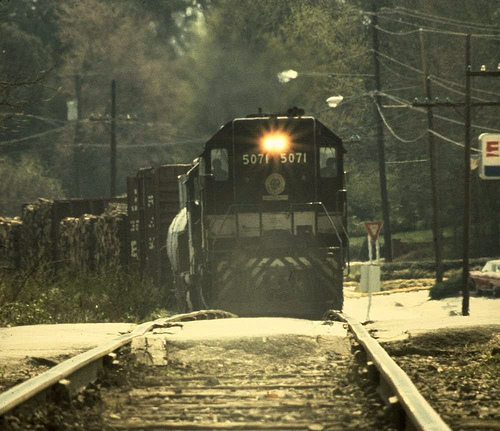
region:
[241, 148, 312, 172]
The numbers on the front of the train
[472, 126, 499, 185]
The large sign by the telephone wires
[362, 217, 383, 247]
The red and white yield sign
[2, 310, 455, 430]
The tracks the train is on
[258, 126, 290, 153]
The light on the front of the train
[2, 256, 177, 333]
The tall grass next to the train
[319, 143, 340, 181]
The window on the right side of the train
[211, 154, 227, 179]
The person shown in the left window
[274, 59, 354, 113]
The street lights seen above the train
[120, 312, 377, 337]
Where road crosses the train tracks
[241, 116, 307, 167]
The train's headlight.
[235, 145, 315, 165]
The train's number.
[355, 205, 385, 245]
A triangular street sign.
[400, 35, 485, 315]
A slender utility pole.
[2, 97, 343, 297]
The train is hauling cargo.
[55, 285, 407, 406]
Train tracks.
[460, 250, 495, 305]
A parked car.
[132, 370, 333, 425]
Wooden planks in gravel.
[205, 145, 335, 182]
The train's conductors can be seen in the windows.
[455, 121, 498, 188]
A large business sign.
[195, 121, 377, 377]
train coming down tracks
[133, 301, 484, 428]
train track crossing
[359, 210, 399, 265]
red and white yield sign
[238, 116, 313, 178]
light on front of train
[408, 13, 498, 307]
wooden power pole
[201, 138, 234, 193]
conductor of train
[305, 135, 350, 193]
conductor of train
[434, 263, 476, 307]
green brush around bottom of power pole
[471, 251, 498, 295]
car parked in parking lot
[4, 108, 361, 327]
train engine pulling cars of wood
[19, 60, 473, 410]
freight train on railroad tracks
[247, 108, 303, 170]
headlight on locomotive engine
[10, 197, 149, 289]
cars loaded with pulp wood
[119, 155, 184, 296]
box car behind engine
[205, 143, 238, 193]
engineer in cab of engine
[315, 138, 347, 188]
conductor sitting in engine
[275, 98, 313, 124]
train horn on top of engine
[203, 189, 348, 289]
ladders to train entrance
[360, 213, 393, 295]
red and white traffic sign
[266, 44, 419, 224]
street lamps beside train tracks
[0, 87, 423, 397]
a train coming on the train tracks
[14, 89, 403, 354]
a train approaching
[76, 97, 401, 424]
a railroad track with a train on it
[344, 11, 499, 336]
a bunch of utility poles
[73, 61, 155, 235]
utility pole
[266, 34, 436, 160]
two streetlights on utility poles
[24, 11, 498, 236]
a forest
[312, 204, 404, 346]
red and white yield sign next to a train track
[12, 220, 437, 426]
a railroad track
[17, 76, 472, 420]
train coming along a railroad track